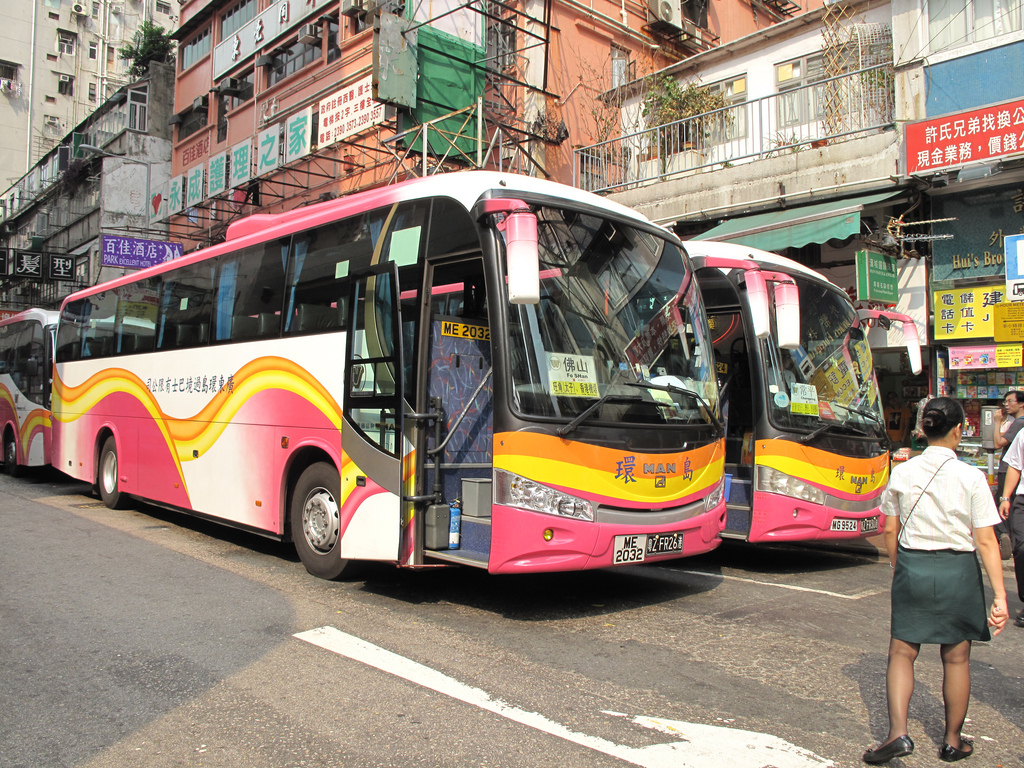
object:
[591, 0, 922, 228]
wall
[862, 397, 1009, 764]
woman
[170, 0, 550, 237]
wall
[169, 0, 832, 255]
building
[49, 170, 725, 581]
bus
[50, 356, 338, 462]
stripes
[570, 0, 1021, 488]
building